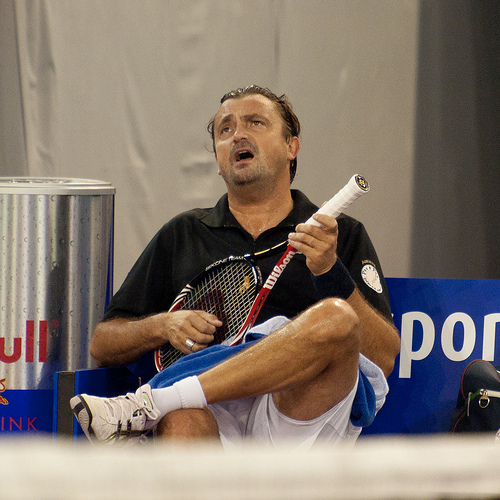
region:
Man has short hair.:
[226, 75, 316, 136]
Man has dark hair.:
[203, 67, 315, 129]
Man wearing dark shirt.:
[181, 205, 270, 252]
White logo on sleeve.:
[356, 260, 393, 306]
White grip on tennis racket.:
[295, 185, 375, 272]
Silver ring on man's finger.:
[181, 329, 211, 370]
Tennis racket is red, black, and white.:
[146, 252, 285, 356]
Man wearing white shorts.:
[246, 408, 301, 446]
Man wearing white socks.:
[163, 370, 197, 423]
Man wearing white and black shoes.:
[82, 381, 154, 450]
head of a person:
[191, 56, 317, 196]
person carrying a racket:
[138, 178, 392, 392]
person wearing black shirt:
[75, 172, 423, 366]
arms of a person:
[66, 291, 243, 378]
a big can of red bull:
[6, 173, 123, 458]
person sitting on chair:
[107, 84, 402, 431]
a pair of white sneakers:
[65, 357, 175, 471]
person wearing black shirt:
[55, 77, 453, 464]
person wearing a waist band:
[286, 204, 380, 316]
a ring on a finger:
[165, 316, 216, 372]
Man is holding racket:
[97, 89, 399, 448]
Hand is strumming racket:
[110, 242, 280, 393]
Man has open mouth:
[202, 97, 299, 195]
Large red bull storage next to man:
[0, 168, 115, 458]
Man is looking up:
[207, 95, 296, 202]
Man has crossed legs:
[90, 279, 367, 471]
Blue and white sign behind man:
[368, 260, 498, 439]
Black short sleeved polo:
[102, 176, 406, 388]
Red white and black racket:
[137, 160, 373, 382]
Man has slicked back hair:
[195, 73, 311, 205]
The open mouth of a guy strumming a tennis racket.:
[230, 145, 253, 162]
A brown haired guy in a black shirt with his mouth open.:
[69, 83, 399, 443]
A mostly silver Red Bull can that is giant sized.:
[1, 173, 116, 439]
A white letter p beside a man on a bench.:
[398, 309, 434, 379]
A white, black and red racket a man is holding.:
[154, 174, 369, 376]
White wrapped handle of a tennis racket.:
[301, 170, 367, 239]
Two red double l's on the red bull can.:
[26, 318, 49, 363]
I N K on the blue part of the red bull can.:
[1, 415, 37, 431]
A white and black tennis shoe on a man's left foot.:
[68, 384, 160, 444]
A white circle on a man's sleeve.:
[360, 264, 384, 294]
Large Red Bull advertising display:
[3, 171, 123, 438]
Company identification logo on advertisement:
[3, 312, 53, 442]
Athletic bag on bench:
[451, 357, 497, 430]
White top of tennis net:
[4, 439, 496, 498]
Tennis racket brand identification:
[257, 246, 299, 291]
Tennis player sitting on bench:
[57, 79, 403, 451]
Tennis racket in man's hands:
[142, 173, 380, 372]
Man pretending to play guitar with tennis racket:
[32, 82, 403, 447]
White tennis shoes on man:
[70, 383, 156, 445]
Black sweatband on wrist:
[309, 257, 356, 303]